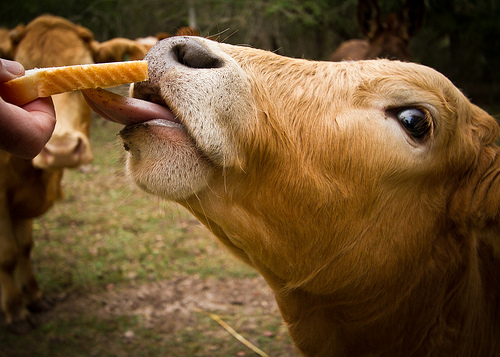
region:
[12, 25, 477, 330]
cow being fed a piece of food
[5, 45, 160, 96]
brown edge of a slice of white bread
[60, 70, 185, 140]
animal tongue touching the bottom of bread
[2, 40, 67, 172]
curled hand holding edge of bread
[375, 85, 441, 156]
glassy round dark eye of cow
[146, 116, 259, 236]
a few long white whiskers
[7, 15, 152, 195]
a cow in the background watching the feeding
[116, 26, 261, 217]
cream colored muzzle with large pores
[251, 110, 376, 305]
fur curving on cow's face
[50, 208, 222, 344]
grass and dirt by the cows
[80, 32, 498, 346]
brown cow eating bread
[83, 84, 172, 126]
red tongue sticking out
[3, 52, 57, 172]
hand holding piece of bread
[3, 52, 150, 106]
piece if white bread near cow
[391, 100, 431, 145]
brown eye on cow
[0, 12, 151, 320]
cow standing behind hand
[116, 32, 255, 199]
white mouth of cow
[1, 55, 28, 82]
nail on thumb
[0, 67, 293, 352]
green and brown grass on ground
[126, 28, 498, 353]
light brown cow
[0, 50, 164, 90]
This is a piece of bread.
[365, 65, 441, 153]
This is an eye.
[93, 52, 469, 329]
This is a cow.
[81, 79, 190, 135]
This is a tongue.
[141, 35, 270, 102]
This is a nose.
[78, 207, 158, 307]
This is green grass.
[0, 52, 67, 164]
This is a hand.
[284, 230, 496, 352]
This is a cow's neck.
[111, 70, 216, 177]
This is a cow's mouth.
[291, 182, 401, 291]
This is the color brown.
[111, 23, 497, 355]
a furry animal with a tongue out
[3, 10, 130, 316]
a light brown cow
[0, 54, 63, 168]
part of a person's hand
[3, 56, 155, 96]
piece of white bread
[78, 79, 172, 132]
long pink animal tongue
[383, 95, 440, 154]
big dark colored eyeball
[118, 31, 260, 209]
white nose and mouth area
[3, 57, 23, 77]
thumb nail on a person's hand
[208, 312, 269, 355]
a piece of straw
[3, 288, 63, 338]
pair of front hooves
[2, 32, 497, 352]
Person is feeding animal bread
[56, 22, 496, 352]
Animal is licking bread with its tougue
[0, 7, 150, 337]
Carmel colored animal in the background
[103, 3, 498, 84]
Trees and animals are in the background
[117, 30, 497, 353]
Cow in front of the camera is Carmel colored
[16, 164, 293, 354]
Grass is green with a big burn patch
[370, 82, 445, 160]
Animals eye is looking down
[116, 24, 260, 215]
Animal has a white colored mouth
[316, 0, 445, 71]
Dark brown colored animal in the background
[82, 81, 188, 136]
Animals tongue is light pink colored